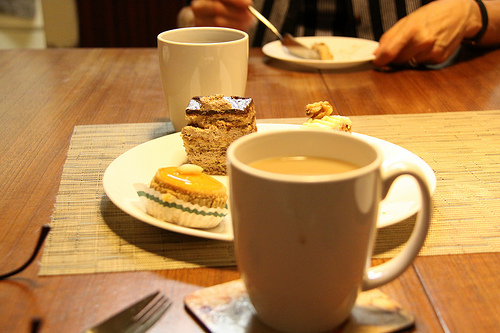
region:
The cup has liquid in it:
[206, 140, 406, 280]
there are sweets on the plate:
[160, 108, 240, 216]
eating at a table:
[43, 14, 455, 320]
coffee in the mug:
[232, 118, 394, 197]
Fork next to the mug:
[95, 289, 176, 331]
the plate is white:
[64, 110, 441, 270]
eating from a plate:
[262, 21, 399, 83]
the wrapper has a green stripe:
[142, 168, 215, 217]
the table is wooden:
[0, 33, 140, 250]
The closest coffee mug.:
[222, 126, 430, 332]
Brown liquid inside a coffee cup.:
[243, 154, 355, 179]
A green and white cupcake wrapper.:
[132, 182, 229, 227]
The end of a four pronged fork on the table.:
[86, 289, 173, 332]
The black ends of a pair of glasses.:
[1, 222, 51, 332]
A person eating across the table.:
[178, 1, 499, 67]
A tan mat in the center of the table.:
[37, 122, 499, 276]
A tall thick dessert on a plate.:
[183, 94, 255, 174]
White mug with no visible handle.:
[157, 25, 251, 131]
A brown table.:
[0, 47, 499, 332]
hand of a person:
[379, 8, 499, 73]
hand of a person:
[188, 2, 277, 53]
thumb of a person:
[357, 16, 387, 63]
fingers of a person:
[363, 18, 458, 86]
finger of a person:
[198, 2, 260, 39]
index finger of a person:
[373, 22, 419, 61]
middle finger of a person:
[403, 39, 425, 68]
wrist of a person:
[466, 4, 486, 46]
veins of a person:
[428, 5, 470, 58]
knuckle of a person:
[417, 35, 430, 46]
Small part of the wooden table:
[14, 155, 39, 182]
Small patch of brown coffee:
[280, 158, 301, 174]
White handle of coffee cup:
[376, 161, 433, 293]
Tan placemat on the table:
[438, 120, 478, 163]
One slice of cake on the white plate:
[184, 95, 220, 167]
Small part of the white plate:
[125, 151, 139, 168]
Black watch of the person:
[480, 7, 488, 41]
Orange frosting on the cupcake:
[166, 170, 184, 182]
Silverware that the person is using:
[249, 5, 301, 59]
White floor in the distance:
[6, 33, 36, 48]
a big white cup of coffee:
[225, 129, 432, 301]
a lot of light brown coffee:
[268, 145, 332, 189]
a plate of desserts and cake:
[122, 102, 254, 236]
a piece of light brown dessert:
[155, 161, 217, 256]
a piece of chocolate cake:
[185, 78, 247, 166]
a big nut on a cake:
[298, 95, 346, 130]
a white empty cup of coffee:
[138, 11, 246, 96]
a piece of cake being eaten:
[274, 21, 361, 81]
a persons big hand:
[380, 18, 467, 86]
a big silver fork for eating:
[84, 281, 174, 332]